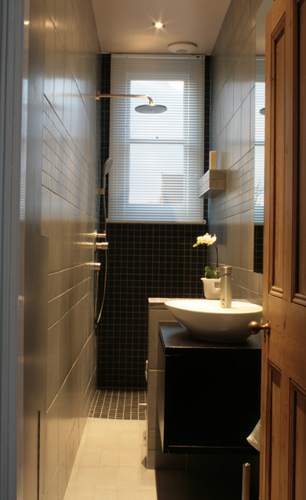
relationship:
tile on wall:
[96, 52, 208, 388] [1, 0, 273, 498]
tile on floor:
[97, 449, 134, 486] [83, 386, 145, 499]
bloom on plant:
[193, 232, 216, 246] [190, 232, 228, 301]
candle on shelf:
[208, 147, 218, 171] [195, 166, 226, 191]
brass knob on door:
[247, 317, 270, 334] [264, 0, 303, 368]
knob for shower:
[95, 240, 108, 248] [87, 52, 213, 420]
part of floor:
[87, 386, 144, 420] [65, 382, 155, 498]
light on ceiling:
[152, 18, 165, 29] [92, 0, 231, 57]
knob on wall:
[94, 240, 109, 250] [29, 1, 100, 498]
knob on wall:
[91, 260, 102, 271] [29, 1, 100, 498]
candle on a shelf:
[206, 148, 217, 170] [196, 166, 227, 198]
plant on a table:
[190, 232, 228, 301] [144, 292, 246, 470]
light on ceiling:
[153, 19, 163, 30] [92, 0, 231, 57]